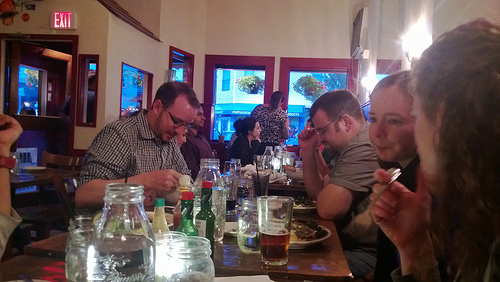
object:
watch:
[0, 153, 16, 172]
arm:
[0, 113, 23, 266]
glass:
[259, 195, 294, 265]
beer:
[261, 226, 289, 265]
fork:
[339, 167, 403, 240]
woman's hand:
[370, 163, 431, 246]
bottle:
[194, 179, 216, 260]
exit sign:
[50, 11, 78, 30]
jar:
[238, 197, 262, 255]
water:
[238, 225, 263, 254]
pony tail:
[268, 90, 283, 110]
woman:
[250, 89, 290, 157]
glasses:
[314, 115, 345, 136]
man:
[298, 88, 381, 278]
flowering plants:
[235, 76, 266, 94]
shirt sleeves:
[73, 126, 133, 193]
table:
[0, 161, 353, 281]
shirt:
[75, 107, 194, 217]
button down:
[156, 139, 166, 170]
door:
[2, 33, 76, 206]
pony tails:
[233, 118, 247, 136]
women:
[230, 118, 261, 164]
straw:
[59, 192, 86, 234]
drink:
[65, 216, 96, 281]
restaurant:
[1, 0, 500, 281]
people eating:
[365, 16, 499, 281]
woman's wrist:
[1, 141, 16, 180]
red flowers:
[293, 75, 328, 101]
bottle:
[88, 179, 154, 282]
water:
[87, 234, 156, 281]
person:
[73, 79, 200, 221]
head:
[152, 80, 198, 143]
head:
[365, 72, 419, 164]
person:
[370, 70, 420, 280]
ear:
[153, 98, 161, 115]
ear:
[341, 114, 353, 133]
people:
[181, 102, 216, 178]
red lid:
[201, 180, 213, 189]